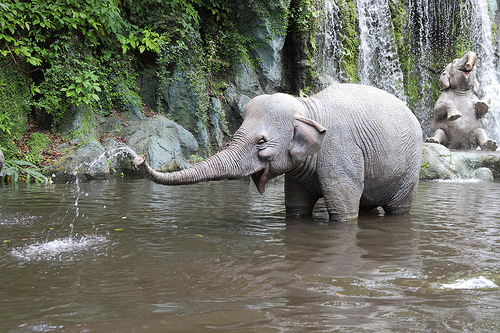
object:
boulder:
[53, 110, 126, 181]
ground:
[437, 147, 459, 174]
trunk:
[131, 141, 248, 188]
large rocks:
[137, 108, 200, 154]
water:
[50, 292, 94, 319]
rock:
[70, 125, 122, 151]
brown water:
[88, 199, 197, 280]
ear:
[289, 115, 327, 166]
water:
[97, 189, 140, 219]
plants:
[120, 32, 177, 74]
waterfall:
[306, 7, 347, 80]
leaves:
[0, 0, 40, 28]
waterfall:
[386, 5, 431, 67]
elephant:
[132, 82, 424, 222]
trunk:
[461, 49, 475, 73]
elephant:
[423, 52, 497, 150]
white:
[480, 64, 499, 99]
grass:
[393, 19, 465, 55]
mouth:
[245, 167, 268, 194]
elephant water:
[84, 131, 145, 206]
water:
[462, 10, 496, 43]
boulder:
[422, 142, 454, 180]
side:
[5, 4, 322, 172]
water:
[457, 232, 496, 251]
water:
[72, 241, 124, 265]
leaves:
[46, 14, 78, 37]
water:
[377, 221, 420, 239]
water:
[0, 260, 40, 306]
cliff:
[98, 0, 143, 138]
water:
[63, 142, 133, 234]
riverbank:
[36, 137, 104, 179]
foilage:
[0, 112, 60, 184]